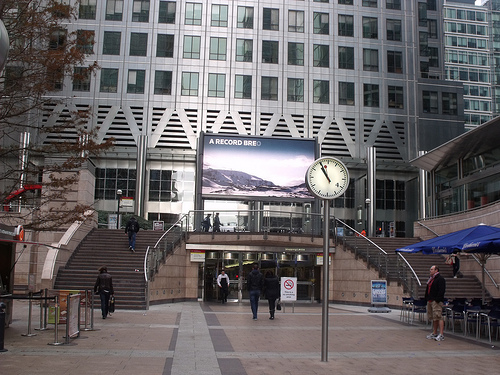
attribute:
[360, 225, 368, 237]
orange jacket — bright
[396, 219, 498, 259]
blue umbrella — big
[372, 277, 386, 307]
logo — small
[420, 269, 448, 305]
shirt — black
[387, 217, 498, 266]
umbrella — blue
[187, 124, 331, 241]
sign — big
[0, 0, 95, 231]
trees — pictured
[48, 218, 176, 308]
stairs — pictured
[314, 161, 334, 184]
hand — black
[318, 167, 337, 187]
hand — black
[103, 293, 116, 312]
briefcase — black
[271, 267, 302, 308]
sign — no smoking sign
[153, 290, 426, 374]
walkway — brick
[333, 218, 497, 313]
stairs — pictured